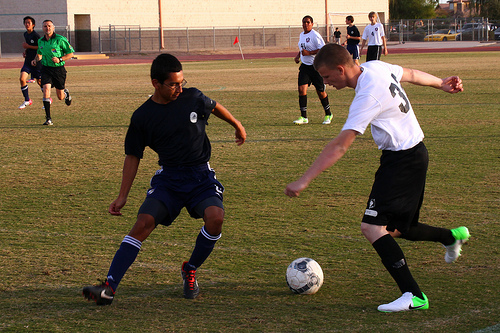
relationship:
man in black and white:
[289, 44, 471, 312] [349, 59, 430, 229]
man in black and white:
[289, 39, 473, 313] [299, 31, 323, 89]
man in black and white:
[289, 39, 473, 313] [363, 22, 386, 60]